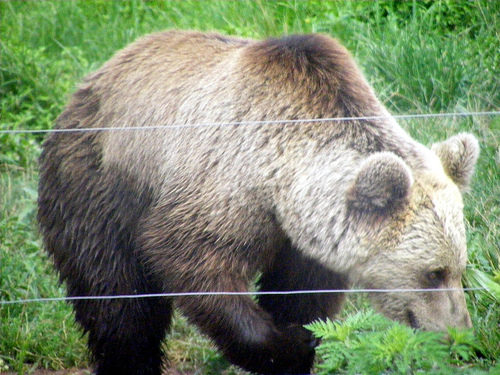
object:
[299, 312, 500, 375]
grass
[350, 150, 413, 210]
ear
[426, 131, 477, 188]
ear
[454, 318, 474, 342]
nose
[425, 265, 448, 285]
eye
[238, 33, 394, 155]
streak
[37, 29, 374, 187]
back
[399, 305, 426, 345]
mouth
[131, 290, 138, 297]
crumbs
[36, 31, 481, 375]
bear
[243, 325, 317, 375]
paw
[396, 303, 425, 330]
mouth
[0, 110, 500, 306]
fence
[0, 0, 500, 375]
ground